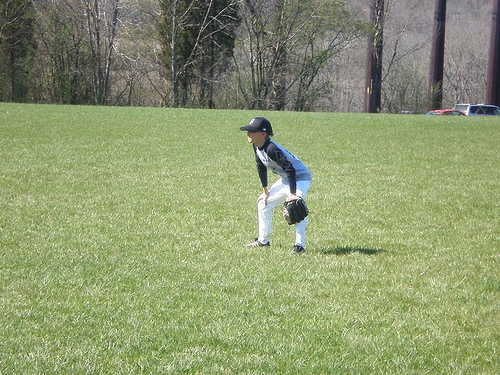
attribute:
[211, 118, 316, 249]
boy — baseball, hat, wearing, standing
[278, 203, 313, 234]
mitt — baseball, black, catching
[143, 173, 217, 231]
area — grassy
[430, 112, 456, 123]
car — red, distant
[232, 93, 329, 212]
person — wearing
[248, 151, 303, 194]
shirt — sleeves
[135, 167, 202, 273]
grass — green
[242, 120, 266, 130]
cap — blue, baseball, boy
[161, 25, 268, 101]
tree — few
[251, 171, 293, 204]
sleeve — long, shirt, black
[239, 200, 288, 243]
pant — white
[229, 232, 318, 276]
shoe — black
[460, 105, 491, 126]
van — white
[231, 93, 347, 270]
player — baseball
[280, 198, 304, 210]
glove — baseball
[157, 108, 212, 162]
field — grassy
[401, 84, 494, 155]
vehicle — background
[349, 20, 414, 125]
pole — three